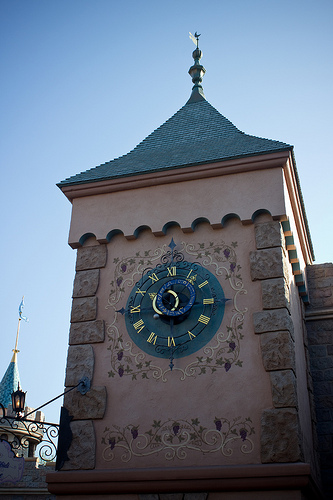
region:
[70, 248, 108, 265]
THAT IS A BRICK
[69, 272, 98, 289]
THAT IS A BRICK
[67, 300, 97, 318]
THAT IS A BRICK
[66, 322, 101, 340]
THAT IS A BRICK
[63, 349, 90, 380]
THAT IS A BRICK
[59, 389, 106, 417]
THAT IS A BRICK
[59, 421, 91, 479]
THAT IS A BRICK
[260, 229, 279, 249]
THAT IS A BRICK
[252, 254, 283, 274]
THAT IS A BRICK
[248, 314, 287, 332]
THAT IS A BRICK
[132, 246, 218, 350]
A CLOCK ON THE BULDING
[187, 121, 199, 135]
THE ROOF OF THE BULDING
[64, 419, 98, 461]
THAT IS A BRICK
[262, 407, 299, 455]
THAT IS A BRICK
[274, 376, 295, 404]
THAT IS A BRICK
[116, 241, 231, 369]
A decorative clock on a clock tower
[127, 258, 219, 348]
Brass roman numerals of an outdoor clock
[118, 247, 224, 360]
An outdoor clock with polished brass roman numerals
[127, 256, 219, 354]
An outdoor clock with brass roman numerals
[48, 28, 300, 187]
A small copper patina roof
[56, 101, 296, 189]
A green copper patina roof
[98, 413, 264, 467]
Painting og purple graps and ivory scrollwork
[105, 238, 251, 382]
An outdoor clock with hand painted cream colored scroll work and purple grapes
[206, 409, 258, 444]
Hand painted purple grapes on vines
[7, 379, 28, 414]
A black and amber glowing decorative lantern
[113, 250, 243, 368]
clock on a tower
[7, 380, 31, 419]
light attached to building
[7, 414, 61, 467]
black metal scroll of a street lamp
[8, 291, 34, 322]
flag on top of a building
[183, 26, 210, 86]
decorative top of a tower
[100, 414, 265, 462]
design on a clock tower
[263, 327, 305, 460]
stone facade on a tower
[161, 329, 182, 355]
golden roman numeral six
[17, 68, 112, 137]
blue clear sky in the distance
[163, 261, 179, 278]
golden roman numeral twelve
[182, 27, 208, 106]
The top of the tower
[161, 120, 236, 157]
The roof of the building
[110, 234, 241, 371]
The clock on the wall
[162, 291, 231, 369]
The hands on the clock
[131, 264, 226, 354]
The clock is the color teal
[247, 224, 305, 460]
The side of the building is stone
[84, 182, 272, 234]
The side of the building is beige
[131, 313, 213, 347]
The clock is in roman numerals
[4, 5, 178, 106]
The sky is clear and blue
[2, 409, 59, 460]
The gate is made of iron